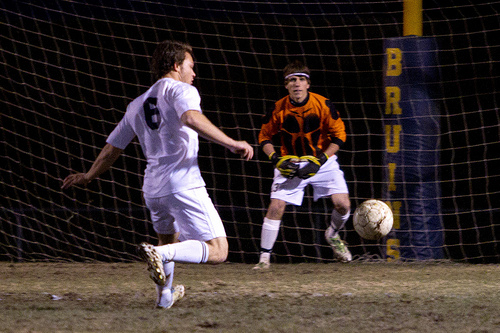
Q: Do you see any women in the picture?
A: No, there are no women.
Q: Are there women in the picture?
A: No, there are no women.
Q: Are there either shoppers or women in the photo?
A: No, there are no women or shoppers.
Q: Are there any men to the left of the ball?
A: Yes, there is a man to the left of the ball.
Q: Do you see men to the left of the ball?
A: Yes, there is a man to the left of the ball.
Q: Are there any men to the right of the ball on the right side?
A: No, the man is to the left of the ball.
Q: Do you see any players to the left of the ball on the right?
A: No, there is a man to the left of the ball.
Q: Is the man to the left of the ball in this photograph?
A: Yes, the man is to the left of the ball.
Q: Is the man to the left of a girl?
A: No, the man is to the left of the ball.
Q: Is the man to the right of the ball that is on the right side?
A: No, the man is to the left of the ball.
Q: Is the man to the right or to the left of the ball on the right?
A: The man is to the left of the ball.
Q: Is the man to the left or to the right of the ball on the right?
A: The man is to the left of the ball.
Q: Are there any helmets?
A: No, there are no helmets.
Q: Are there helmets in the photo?
A: No, there are no helmets.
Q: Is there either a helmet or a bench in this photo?
A: No, there are no helmets or benches.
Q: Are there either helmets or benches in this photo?
A: No, there are no helmets or benches.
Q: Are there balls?
A: Yes, there is a ball.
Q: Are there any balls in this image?
A: Yes, there is a ball.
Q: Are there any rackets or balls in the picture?
A: Yes, there is a ball.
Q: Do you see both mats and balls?
A: No, there is a ball but no mats.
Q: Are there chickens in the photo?
A: No, there are no chickens.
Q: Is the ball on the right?
A: Yes, the ball is on the right of the image.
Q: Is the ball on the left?
A: No, the ball is on the right of the image.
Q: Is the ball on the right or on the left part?
A: The ball is on the right of the image.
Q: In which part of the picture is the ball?
A: The ball is on the right of the image.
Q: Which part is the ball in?
A: The ball is on the right of the image.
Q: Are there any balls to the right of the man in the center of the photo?
A: Yes, there is a ball to the right of the man.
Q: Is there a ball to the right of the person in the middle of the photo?
A: Yes, there is a ball to the right of the man.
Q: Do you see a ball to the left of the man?
A: No, the ball is to the right of the man.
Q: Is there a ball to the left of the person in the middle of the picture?
A: No, the ball is to the right of the man.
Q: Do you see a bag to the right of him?
A: No, there is a ball to the right of the man.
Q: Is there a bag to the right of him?
A: No, there is a ball to the right of the man.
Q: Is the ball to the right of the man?
A: Yes, the ball is to the right of the man.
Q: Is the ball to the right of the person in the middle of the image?
A: Yes, the ball is to the right of the man.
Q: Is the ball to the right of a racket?
A: No, the ball is to the right of the man.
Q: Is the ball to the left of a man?
A: No, the ball is to the right of a man.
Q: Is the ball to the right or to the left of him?
A: The ball is to the right of the man.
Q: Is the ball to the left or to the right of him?
A: The ball is to the right of the man.